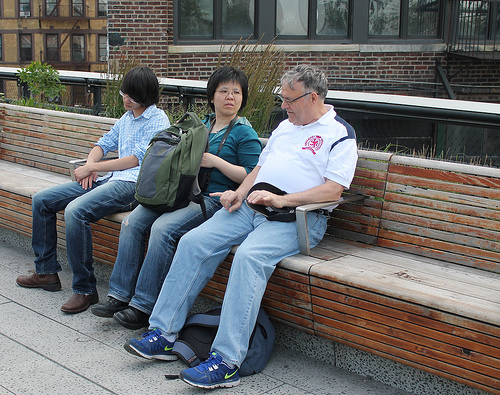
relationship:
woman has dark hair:
[93, 67, 262, 327] [208, 69, 249, 109]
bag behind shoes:
[174, 302, 277, 371] [124, 328, 240, 390]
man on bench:
[122, 63, 358, 389] [3, 106, 500, 391]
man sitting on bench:
[122, 63, 358, 389] [3, 106, 500, 391]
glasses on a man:
[277, 93, 308, 106] [126, 62, 360, 388]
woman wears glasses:
[93, 67, 262, 327] [214, 86, 244, 97]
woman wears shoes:
[93, 67, 262, 327] [90, 292, 146, 327]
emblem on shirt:
[303, 132, 327, 156] [259, 107, 360, 213]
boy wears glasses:
[14, 66, 173, 316] [118, 90, 145, 107]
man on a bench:
[122, 63, 358, 389] [3, 106, 500, 391]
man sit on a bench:
[122, 63, 358, 389] [3, 106, 500, 391]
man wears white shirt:
[126, 62, 360, 388] [259, 107, 360, 213]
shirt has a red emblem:
[259, 107, 360, 213] [298, 133, 324, 155]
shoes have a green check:
[124, 328, 240, 390] [225, 366, 238, 380]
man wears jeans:
[126, 62, 360, 388] [147, 196, 328, 365]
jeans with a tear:
[111, 194, 232, 305] [120, 218, 132, 226]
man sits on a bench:
[126, 62, 360, 388] [3, 106, 500, 391]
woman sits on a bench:
[93, 67, 262, 327] [3, 106, 500, 391]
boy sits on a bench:
[14, 66, 173, 316] [3, 106, 500, 391]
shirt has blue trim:
[259, 107, 360, 213] [327, 113, 354, 156]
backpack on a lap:
[137, 112, 217, 212] [126, 185, 222, 221]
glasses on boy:
[118, 90, 145, 107] [14, 66, 173, 316]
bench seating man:
[3, 106, 500, 391] [122, 63, 358, 389]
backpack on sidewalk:
[137, 112, 217, 212] [1, 223, 500, 392]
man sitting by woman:
[126, 62, 360, 388] [93, 67, 262, 327]